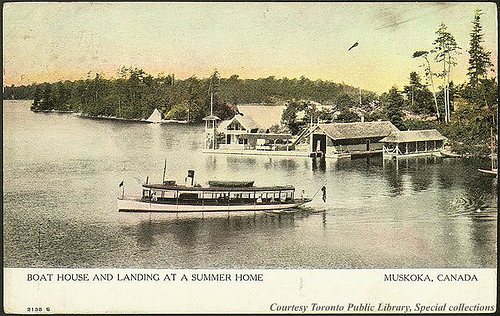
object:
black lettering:
[25, 273, 264, 282]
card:
[0, 0, 500, 316]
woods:
[2, 64, 378, 122]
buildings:
[215, 105, 341, 152]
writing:
[383, 273, 479, 282]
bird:
[346, 39, 361, 51]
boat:
[476, 127, 499, 176]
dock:
[378, 128, 446, 166]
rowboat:
[208, 180, 255, 187]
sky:
[2, 2, 497, 100]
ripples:
[437, 186, 490, 217]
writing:
[268, 302, 496, 313]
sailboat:
[145, 108, 163, 126]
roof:
[304, 122, 401, 140]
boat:
[440, 148, 471, 158]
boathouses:
[291, 120, 400, 159]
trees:
[463, 5, 497, 84]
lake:
[2, 99, 498, 268]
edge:
[477, 169, 498, 174]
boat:
[116, 157, 330, 213]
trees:
[28, 81, 53, 111]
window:
[234, 123, 239, 130]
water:
[328, 178, 484, 220]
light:
[1, 66, 127, 87]